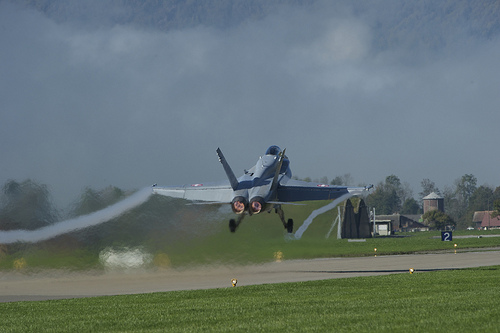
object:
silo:
[418, 191, 444, 231]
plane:
[150, 144, 374, 235]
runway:
[0, 244, 499, 305]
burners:
[229, 198, 247, 214]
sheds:
[338, 194, 358, 237]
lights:
[228, 278, 237, 288]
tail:
[226, 179, 273, 217]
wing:
[151, 183, 235, 207]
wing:
[278, 173, 376, 203]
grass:
[0, 263, 499, 333]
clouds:
[0, 0, 498, 212]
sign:
[441, 230, 454, 242]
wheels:
[284, 217, 294, 234]